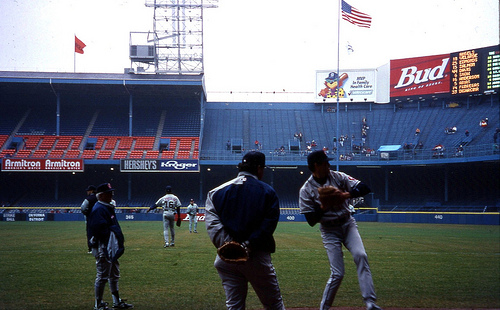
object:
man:
[88, 183, 125, 310]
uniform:
[87, 201, 126, 308]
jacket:
[87, 201, 124, 249]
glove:
[216, 240, 251, 264]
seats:
[203, 104, 500, 156]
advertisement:
[314, 68, 377, 103]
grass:
[0, 221, 500, 310]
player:
[147, 186, 182, 248]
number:
[165, 201, 174, 208]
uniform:
[150, 194, 182, 243]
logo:
[161, 161, 197, 169]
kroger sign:
[161, 161, 197, 170]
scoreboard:
[450, 45, 500, 95]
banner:
[121, 158, 160, 170]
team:
[186, 199, 200, 234]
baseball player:
[299, 149, 373, 309]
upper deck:
[0, 70, 500, 161]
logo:
[3, 159, 83, 170]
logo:
[394, 58, 450, 92]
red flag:
[75, 35, 86, 54]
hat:
[307, 150, 335, 166]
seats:
[0, 108, 201, 159]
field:
[0, 221, 500, 310]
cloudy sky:
[0, 0, 500, 102]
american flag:
[339, 0, 372, 28]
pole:
[336, 0, 341, 171]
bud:
[394, 58, 450, 89]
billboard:
[390, 54, 451, 98]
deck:
[0, 135, 199, 159]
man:
[299, 150, 383, 310]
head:
[306, 150, 330, 174]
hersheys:
[159, 159, 198, 170]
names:
[458, 50, 480, 94]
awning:
[0, 70, 207, 101]